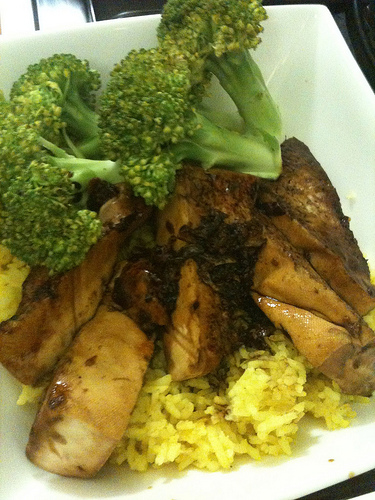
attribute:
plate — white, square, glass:
[2, 1, 374, 498]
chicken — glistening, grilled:
[25, 292, 159, 483]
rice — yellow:
[259, 441, 282, 457]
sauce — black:
[115, 216, 279, 350]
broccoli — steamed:
[99, 1, 292, 208]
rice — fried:
[111, 449, 132, 467]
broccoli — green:
[9, 53, 104, 158]